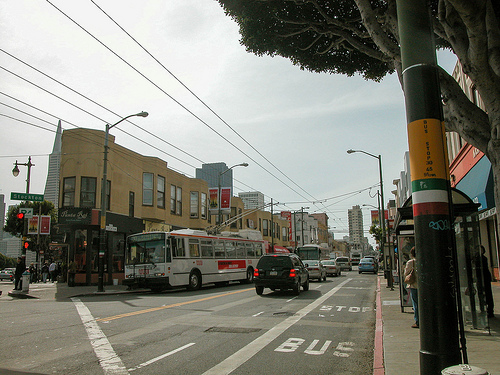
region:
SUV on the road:
[253, 250, 314, 298]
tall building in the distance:
[343, 205, 370, 263]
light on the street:
[6, 156, 26, 181]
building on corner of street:
[59, 127, 287, 292]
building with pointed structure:
[44, 118, 69, 218]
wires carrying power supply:
[6, 13, 336, 213]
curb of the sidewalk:
[369, 321, 387, 373]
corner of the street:
[8, 263, 86, 315]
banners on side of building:
[205, 189, 235, 211]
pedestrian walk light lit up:
[21, 236, 34, 255]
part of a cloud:
[286, 103, 296, 110]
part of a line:
[263, 295, 301, 344]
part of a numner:
[309, 322, 335, 349]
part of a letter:
[282, 319, 295, 345]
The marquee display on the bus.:
[124, 232, 166, 238]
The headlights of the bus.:
[119, 275, 171, 280]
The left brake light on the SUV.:
[252, 268, 259, 275]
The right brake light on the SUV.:
[288, 264, 295, 274]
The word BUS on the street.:
[272, 334, 359, 355]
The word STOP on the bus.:
[322, 300, 372, 315]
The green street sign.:
[12, 193, 45, 201]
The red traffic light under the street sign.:
[18, 214, 25, 229]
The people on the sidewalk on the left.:
[35, 249, 57, 289]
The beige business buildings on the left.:
[65, 134, 299, 279]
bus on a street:
[117, 225, 272, 294]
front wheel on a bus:
[186, 266, 208, 293]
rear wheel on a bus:
[239, 265, 256, 284]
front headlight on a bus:
[150, 269, 168, 281]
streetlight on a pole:
[340, 140, 388, 169]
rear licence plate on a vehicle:
[266, 268, 280, 279]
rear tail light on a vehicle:
[285, 267, 298, 279]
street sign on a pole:
[8, 187, 48, 204]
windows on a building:
[135, 167, 169, 214]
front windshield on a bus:
[120, 229, 170, 268]